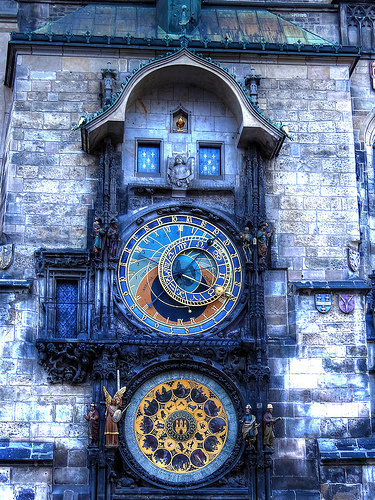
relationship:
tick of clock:
[168, 210, 177, 223] [114, 210, 246, 339]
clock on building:
[122, 210, 243, 336] [0, 0, 371, 499]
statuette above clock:
[167, 153, 192, 192] [122, 210, 243, 336]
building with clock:
[0, 0, 375, 500] [122, 210, 243, 336]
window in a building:
[120, 122, 246, 205] [38, 60, 344, 470]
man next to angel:
[82, 402, 102, 443] [97, 380, 131, 446]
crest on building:
[305, 276, 373, 319] [38, 60, 344, 470]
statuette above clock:
[170, 110, 191, 133] [122, 210, 243, 336]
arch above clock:
[68, 45, 287, 156] [122, 210, 243, 336]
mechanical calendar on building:
[117, 213, 243, 334] [0, 0, 371, 499]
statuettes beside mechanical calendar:
[83, 403, 101, 447] [117, 213, 243, 334]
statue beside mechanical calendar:
[100, 382, 129, 446] [117, 213, 243, 334]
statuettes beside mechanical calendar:
[238, 402, 261, 452] [117, 213, 243, 334]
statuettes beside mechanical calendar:
[261, 403, 282, 450] [117, 213, 243, 334]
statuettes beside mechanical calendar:
[237, 226, 254, 264] [117, 213, 243, 334]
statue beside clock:
[100, 382, 129, 446] [114, 217, 256, 342]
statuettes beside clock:
[238, 402, 261, 452] [114, 217, 256, 342]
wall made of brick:
[0, 53, 374, 499] [305, 360, 359, 410]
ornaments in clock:
[123, 377, 230, 476] [115, 364, 254, 481]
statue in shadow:
[100, 382, 129, 446] [80, 374, 322, 498]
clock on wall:
[114, 210, 246, 339] [0, 53, 374, 499]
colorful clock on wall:
[121, 368, 241, 489] [0, 53, 374, 499]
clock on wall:
[122, 210, 243, 336] [0, 0, 366, 499]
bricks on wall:
[294, 319, 367, 434] [22, 51, 353, 488]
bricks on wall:
[279, 172, 336, 277] [0, 0, 366, 499]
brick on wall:
[12, 399, 55, 422] [0, 53, 374, 499]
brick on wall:
[52, 402, 86, 422] [0, 53, 374, 499]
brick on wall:
[0, 420, 32, 441] [0, 53, 374, 499]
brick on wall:
[30, 420, 72, 438] [0, 53, 374, 499]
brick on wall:
[0, 399, 16, 422] [0, 53, 374, 499]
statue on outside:
[100, 383, 126, 446] [25, 17, 341, 451]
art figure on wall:
[257, 221, 278, 265] [279, 130, 331, 226]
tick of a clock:
[184, 215, 196, 225] [114, 210, 246, 339]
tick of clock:
[191, 321, 205, 339] [122, 210, 243, 336]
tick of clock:
[219, 295, 240, 315] [122, 210, 243, 336]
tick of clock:
[125, 287, 140, 307] [101, 194, 278, 350]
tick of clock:
[117, 264, 141, 280] [118, 197, 213, 304]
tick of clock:
[119, 246, 144, 266] [108, 195, 249, 341]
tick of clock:
[153, 229, 159, 237] [116, 215, 242, 334]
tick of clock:
[150, 226, 163, 241] [106, 192, 257, 352]